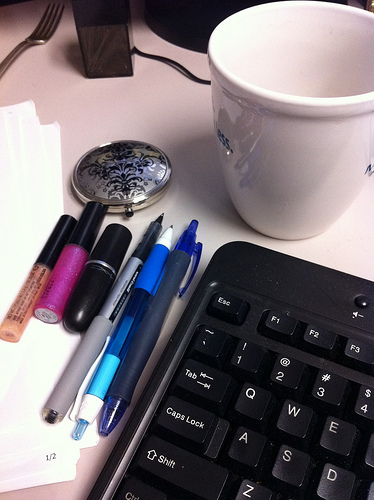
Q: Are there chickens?
A: No, there are no chickens.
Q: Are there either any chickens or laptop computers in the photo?
A: No, there are no chickens or laptop computers.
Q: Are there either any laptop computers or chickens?
A: No, there are no chickens or laptop computers.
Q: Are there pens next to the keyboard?
A: Yes, there are pens next to the keyboard.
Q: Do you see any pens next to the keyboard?
A: Yes, there are pens next to the keyboard.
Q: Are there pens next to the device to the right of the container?
A: Yes, there are pens next to the keyboard.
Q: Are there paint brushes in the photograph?
A: No, there are no paint brushes.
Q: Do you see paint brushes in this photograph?
A: No, there are no paint brushes.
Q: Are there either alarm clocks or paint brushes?
A: No, there are no paint brushes or alarm clocks.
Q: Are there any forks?
A: Yes, there is a fork.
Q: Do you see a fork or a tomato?
A: Yes, there is a fork.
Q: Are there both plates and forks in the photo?
A: No, there is a fork but no plates.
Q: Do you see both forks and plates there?
A: No, there is a fork but no plates.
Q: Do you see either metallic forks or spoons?
A: Yes, there is a metal fork.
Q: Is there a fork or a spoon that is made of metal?
A: Yes, the fork is made of metal.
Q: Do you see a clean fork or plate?
A: Yes, there is a clean fork.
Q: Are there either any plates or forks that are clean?
A: Yes, the fork is clean.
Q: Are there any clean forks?
A: Yes, there is a clean fork.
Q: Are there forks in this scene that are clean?
A: Yes, there is a fork that is clean.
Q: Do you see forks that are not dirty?
A: Yes, there is a clean fork.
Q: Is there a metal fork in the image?
A: Yes, there is a fork that is made of metal.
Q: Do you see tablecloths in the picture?
A: No, there are no tablecloths.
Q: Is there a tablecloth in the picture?
A: No, there are no tablecloths.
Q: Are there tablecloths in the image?
A: No, there are no tablecloths.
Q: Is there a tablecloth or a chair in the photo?
A: No, there are no tablecloths or chairs.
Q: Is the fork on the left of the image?
A: Yes, the fork is on the left of the image.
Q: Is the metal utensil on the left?
A: Yes, the fork is on the left of the image.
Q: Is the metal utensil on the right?
A: No, the fork is on the left of the image.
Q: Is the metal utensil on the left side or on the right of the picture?
A: The fork is on the left of the image.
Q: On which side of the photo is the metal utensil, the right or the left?
A: The fork is on the left of the image.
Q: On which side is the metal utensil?
A: The fork is on the left of the image.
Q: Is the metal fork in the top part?
A: Yes, the fork is in the top of the image.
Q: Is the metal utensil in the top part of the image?
A: Yes, the fork is in the top of the image.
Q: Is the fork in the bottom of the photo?
A: No, the fork is in the top of the image.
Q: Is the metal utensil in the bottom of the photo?
A: No, the fork is in the top of the image.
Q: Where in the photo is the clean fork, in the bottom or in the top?
A: The fork is in the top of the image.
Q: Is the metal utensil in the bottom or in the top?
A: The fork is in the top of the image.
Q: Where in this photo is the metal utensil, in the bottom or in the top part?
A: The fork is in the top of the image.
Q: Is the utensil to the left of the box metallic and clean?
A: Yes, the fork is metallic and clean.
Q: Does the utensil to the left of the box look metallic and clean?
A: Yes, the fork is metallic and clean.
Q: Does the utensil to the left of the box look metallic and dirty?
A: No, the fork is metallic but clean.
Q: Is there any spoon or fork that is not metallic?
A: No, there is a fork but it is metallic.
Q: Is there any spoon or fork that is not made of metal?
A: No, there is a fork but it is made of metal.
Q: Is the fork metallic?
A: Yes, the fork is metallic.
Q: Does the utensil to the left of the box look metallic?
A: Yes, the fork is metallic.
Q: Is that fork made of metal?
A: Yes, the fork is made of metal.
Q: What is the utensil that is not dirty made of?
A: The fork is made of metal.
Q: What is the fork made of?
A: The fork is made of metal.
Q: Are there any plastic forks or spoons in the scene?
A: No, there is a fork but it is metallic.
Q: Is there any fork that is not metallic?
A: No, there is a fork but it is metallic.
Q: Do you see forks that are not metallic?
A: No, there is a fork but it is metallic.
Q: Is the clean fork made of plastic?
A: No, the fork is made of metal.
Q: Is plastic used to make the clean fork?
A: No, the fork is made of metal.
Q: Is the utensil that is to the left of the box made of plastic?
A: No, the fork is made of metal.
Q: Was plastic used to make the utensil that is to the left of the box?
A: No, the fork is made of metal.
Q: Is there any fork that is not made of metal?
A: No, there is a fork but it is made of metal.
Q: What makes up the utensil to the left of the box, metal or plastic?
A: The fork is made of metal.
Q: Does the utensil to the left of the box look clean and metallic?
A: Yes, the fork is clean and metallic.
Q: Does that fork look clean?
A: Yes, the fork is clean.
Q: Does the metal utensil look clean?
A: Yes, the fork is clean.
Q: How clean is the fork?
A: The fork is clean.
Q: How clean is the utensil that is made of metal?
A: The fork is clean.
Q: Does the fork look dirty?
A: No, the fork is clean.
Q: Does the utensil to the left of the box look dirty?
A: No, the fork is clean.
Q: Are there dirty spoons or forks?
A: No, there is a fork but it is clean.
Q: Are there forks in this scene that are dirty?
A: No, there is a fork but it is clean.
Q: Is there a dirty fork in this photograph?
A: No, there is a fork but it is clean.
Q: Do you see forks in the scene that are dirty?
A: No, there is a fork but it is clean.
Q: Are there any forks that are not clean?
A: No, there is a fork but it is clean.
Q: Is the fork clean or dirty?
A: The fork is clean.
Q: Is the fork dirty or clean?
A: The fork is clean.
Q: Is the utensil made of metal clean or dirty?
A: The fork is clean.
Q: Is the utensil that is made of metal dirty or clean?
A: The fork is clean.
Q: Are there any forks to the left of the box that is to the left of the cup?
A: Yes, there is a fork to the left of the box.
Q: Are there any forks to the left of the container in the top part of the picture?
A: Yes, there is a fork to the left of the box.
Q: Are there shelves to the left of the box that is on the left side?
A: No, there is a fork to the left of the box.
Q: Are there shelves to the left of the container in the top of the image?
A: No, there is a fork to the left of the box.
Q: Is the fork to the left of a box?
A: Yes, the fork is to the left of a box.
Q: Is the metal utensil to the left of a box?
A: Yes, the fork is to the left of a box.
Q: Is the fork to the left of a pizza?
A: No, the fork is to the left of a box.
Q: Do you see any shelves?
A: No, there are no shelves.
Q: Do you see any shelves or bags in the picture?
A: No, there are no shelves or bags.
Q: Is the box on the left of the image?
A: Yes, the box is on the left of the image.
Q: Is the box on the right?
A: No, the box is on the left of the image.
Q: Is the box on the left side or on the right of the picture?
A: The box is on the left of the image.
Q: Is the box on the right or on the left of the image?
A: The box is on the left of the image.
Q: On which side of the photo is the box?
A: The box is on the left of the image.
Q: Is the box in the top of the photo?
A: Yes, the box is in the top of the image.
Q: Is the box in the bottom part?
A: No, the box is in the top of the image.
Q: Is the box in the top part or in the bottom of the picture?
A: The box is in the top of the image.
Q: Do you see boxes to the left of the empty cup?
A: Yes, there is a box to the left of the cup.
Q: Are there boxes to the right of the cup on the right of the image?
A: No, the box is to the left of the cup.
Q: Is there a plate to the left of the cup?
A: No, there is a box to the left of the cup.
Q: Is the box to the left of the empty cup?
A: Yes, the box is to the left of the cup.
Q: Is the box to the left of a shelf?
A: No, the box is to the left of the cup.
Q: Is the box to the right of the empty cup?
A: No, the box is to the left of the cup.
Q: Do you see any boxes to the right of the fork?
A: Yes, there is a box to the right of the fork.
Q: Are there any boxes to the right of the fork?
A: Yes, there is a box to the right of the fork.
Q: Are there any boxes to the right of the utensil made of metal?
A: Yes, there is a box to the right of the fork.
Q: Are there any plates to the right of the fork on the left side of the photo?
A: No, there is a box to the right of the fork.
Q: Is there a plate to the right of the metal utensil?
A: No, there is a box to the right of the fork.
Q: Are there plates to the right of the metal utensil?
A: No, there is a box to the right of the fork.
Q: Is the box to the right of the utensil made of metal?
A: Yes, the box is to the right of the fork.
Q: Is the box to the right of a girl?
A: No, the box is to the right of the fork.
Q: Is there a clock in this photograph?
A: No, there are no clocks.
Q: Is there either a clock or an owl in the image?
A: No, there are no clocks or owls.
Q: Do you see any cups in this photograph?
A: Yes, there is a cup.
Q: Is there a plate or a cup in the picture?
A: Yes, there is a cup.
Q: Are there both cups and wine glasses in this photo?
A: No, there is a cup but no wine glasses.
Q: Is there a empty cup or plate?
A: Yes, there is an empty cup.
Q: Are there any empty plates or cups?
A: Yes, there is an empty cup.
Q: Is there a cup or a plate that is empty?
A: Yes, the cup is empty.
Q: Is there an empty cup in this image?
A: Yes, there is an empty cup.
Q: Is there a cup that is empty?
A: Yes, there is a cup that is empty.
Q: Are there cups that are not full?
A: Yes, there is a empty cup.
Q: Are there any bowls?
A: No, there are no bowls.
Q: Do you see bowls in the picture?
A: No, there are no bowls.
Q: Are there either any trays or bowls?
A: No, there are no bowls or trays.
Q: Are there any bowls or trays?
A: No, there are no bowls or trays.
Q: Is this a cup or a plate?
A: This is a cup.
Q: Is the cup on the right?
A: Yes, the cup is on the right of the image.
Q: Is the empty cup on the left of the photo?
A: No, the cup is on the right of the image.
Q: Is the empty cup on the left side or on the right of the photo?
A: The cup is on the right of the image.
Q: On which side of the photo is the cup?
A: The cup is on the right of the image.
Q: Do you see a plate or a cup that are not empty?
A: No, there is a cup but it is empty.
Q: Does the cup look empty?
A: Yes, the cup is empty.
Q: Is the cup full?
A: No, the cup is empty.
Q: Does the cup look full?
A: No, the cup is empty.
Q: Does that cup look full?
A: No, the cup is empty.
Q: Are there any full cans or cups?
A: No, there is a cup but it is empty.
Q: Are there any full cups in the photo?
A: No, there is a cup but it is empty.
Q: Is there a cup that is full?
A: No, there is a cup but it is empty.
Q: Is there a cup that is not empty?
A: No, there is a cup but it is empty.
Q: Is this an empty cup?
A: Yes, this is an empty cup.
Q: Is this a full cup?
A: No, this is an empty cup.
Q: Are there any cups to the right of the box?
A: Yes, there is a cup to the right of the box.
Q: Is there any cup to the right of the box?
A: Yes, there is a cup to the right of the box.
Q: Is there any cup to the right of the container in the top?
A: Yes, there is a cup to the right of the box.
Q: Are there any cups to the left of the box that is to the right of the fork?
A: No, the cup is to the right of the box.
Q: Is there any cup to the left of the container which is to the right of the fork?
A: No, the cup is to the right of the box.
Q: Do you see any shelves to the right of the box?
A: No, there is a cup to the right of the box.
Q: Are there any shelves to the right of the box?
A: No, there is a cup to the right of the box.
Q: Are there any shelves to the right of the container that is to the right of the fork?
A: No, there is a cup to the right of the box.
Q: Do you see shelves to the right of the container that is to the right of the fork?
A: No, there is a cup to the right of the box.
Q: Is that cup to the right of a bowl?
A: No, the cup is to the right of the box.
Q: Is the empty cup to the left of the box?
A: No, the cup is to the right of the box.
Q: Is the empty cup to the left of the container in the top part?
A: No, the cup is to the right of the box.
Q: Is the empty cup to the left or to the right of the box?
A: The cup is to the right of the box.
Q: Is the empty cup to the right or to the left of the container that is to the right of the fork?
A: The cup is to the right of the box.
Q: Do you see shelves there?
A: No, there are no shelves.